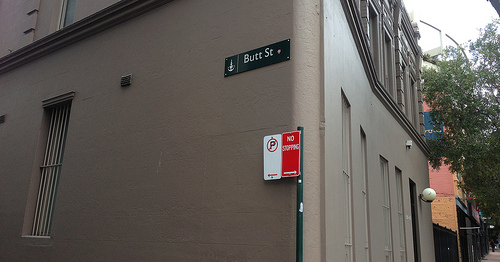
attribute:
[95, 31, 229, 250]
facade — grey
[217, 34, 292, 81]
sign — green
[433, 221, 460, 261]
fence — black, metal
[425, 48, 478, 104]
leaves — green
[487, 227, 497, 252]
person — distant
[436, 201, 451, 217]
brick — orange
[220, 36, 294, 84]
sign — black, white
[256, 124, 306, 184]
sign — white, red, black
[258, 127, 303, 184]
sign — red, white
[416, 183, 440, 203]
lamp — white, round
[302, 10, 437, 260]
concrete — beige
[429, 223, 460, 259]
fence — metal, black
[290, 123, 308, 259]
pole — green, metal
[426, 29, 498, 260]
tree — large, green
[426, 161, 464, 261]
building — peach, orange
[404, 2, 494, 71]
sky — pale, white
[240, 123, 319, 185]
sign — red, white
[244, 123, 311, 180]
circle — red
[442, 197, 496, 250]
fence — black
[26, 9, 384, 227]
building — tan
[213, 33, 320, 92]
sign — black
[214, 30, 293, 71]
letters — white